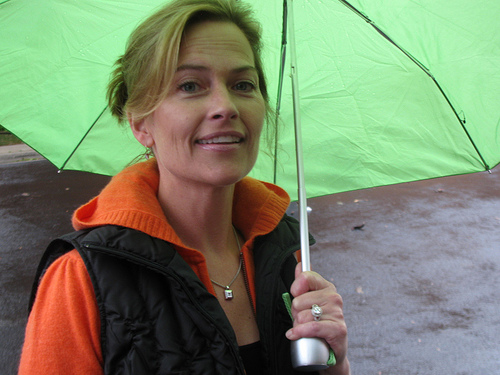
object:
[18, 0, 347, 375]
woman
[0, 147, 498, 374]
street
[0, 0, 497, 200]
umbrella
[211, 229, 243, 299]
necklace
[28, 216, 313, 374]
vest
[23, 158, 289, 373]
sweater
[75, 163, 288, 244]
hood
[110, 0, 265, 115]
hair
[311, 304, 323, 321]
ring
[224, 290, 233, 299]
pendant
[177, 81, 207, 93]
eye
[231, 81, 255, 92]
eye